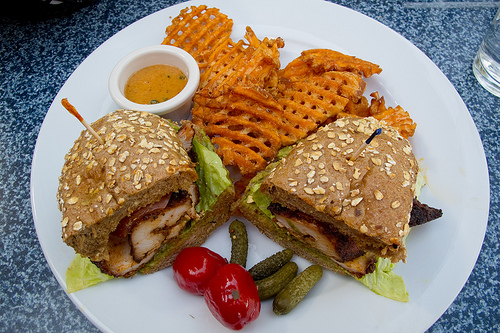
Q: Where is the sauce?
A: In the small cup.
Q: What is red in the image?
A: Tomatoes.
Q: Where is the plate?
A: On a table.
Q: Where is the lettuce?
A: In the sandwich.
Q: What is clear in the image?
A: The glass.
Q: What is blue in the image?
A: The table top.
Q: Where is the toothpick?
A: In the sandwich.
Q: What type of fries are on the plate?
A: Waffle fries.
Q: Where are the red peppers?
A: On the plate.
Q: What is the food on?
A: A white plate.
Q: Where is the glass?
A: The right of the plate.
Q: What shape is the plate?
A: A circle.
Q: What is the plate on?
A: Speckled table.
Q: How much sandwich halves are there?
A: Two.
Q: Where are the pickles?
A: Behind the peppers.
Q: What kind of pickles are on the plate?
A: Baby pickles.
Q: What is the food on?
A: Plate.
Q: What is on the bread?
A: Oats.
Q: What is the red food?
A: Tomatoes.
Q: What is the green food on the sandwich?
A: Lettuce.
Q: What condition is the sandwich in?
A: Cut.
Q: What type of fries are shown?
A: Waffle fries.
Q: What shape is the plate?
A: Round.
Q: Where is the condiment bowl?
A: Beside the fries.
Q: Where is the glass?
A: Top right of the image.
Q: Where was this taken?
A: A restaurant.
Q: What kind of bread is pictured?
A: Sesame buns.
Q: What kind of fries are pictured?
A: Orange waffle fries.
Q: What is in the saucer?
A: An orange dipping sauce or condiment.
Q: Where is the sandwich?
A: On a plate.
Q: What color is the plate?
A: White.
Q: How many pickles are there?
A: 4.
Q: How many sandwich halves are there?
A: 2.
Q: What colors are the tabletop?
A: Blue and white.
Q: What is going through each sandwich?
A: Toothpicks.